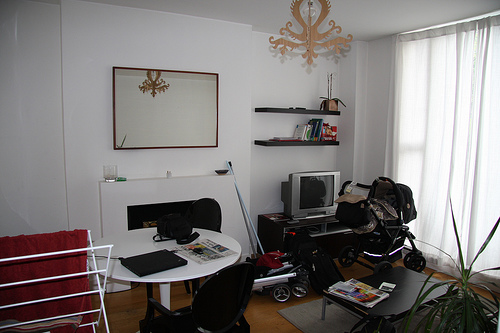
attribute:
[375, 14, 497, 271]
drape — white, long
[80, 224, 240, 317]
table — white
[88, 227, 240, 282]
top — round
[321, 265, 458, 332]
table — small, wooden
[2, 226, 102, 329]
blanket — red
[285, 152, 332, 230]
television set — gray-and-black, tube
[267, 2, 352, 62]
light fixture — decorative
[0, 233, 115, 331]
blanket rack — white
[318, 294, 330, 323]
legs — metal